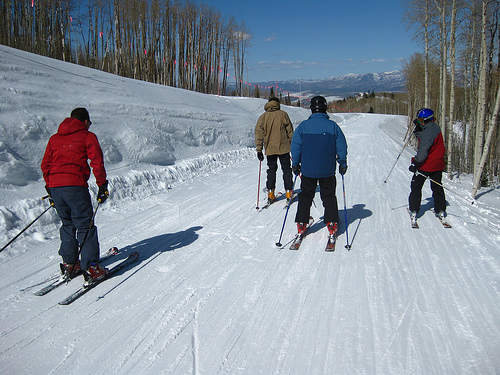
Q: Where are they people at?
A: Snow slope.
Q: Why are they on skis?
A: To ski.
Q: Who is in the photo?
A: 4 people.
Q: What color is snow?
A: White.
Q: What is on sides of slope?
A: Trees.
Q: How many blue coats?
A: One.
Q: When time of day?
A: Daytime.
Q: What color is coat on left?
A: Red.